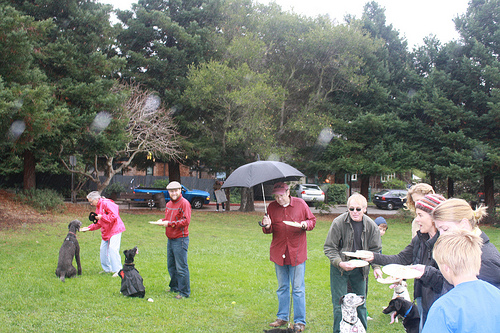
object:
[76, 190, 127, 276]
woman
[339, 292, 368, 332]
dog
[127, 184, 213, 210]
truck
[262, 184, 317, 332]
man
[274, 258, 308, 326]
jeans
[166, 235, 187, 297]
jeans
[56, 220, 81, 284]
dog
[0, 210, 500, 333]
grass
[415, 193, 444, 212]
hat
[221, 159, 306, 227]
black umbrella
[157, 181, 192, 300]
man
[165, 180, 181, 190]
hat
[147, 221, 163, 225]
plate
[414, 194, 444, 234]
head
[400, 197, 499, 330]
woman